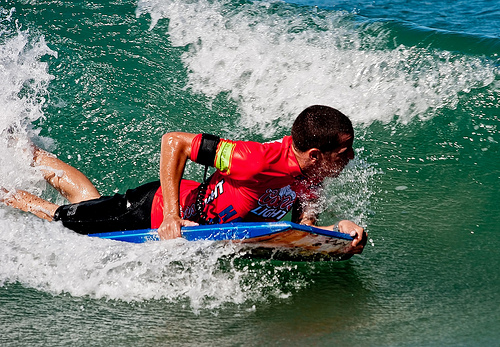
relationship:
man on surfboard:
[4, 100, 356, 226] [90, 223, 360, 258]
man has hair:
[4, 100, 356, 226] [285, 104, 358, 144]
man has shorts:
[4, 100, 356, 226] [53, 167, 161, 238]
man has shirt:
[4, 100, 356, 226] [148, 127, 312, 233]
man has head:
[4, 100, 356, 226] [288, 97, 361, 181]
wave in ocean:
[170, 12, 489, 121] [13, 20, 499, 331]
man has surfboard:
[4, 100, 356, 226] [90, 223, 360, 258]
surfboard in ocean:
[90, 223, 360, 258] [13, 20, 499, 331]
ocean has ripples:
[13, 20, 499, 331] [381, 217, 491, 276]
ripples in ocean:
[381, 217, 491, 276] [13, 20, 499, 331]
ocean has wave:
[13, 20, 499, 331] [170, 12, 489, 121]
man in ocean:
[4, 100, 356, 226] [13, 20, 499, 331]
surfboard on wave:
[90, 223, 360, 258] [170, 12, 489, 121]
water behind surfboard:
[5, 40, 65, 289] [90, 223, 360, 258]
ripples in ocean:
[28, 305, 181, 343] [13, 20, 499, 331]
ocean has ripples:
[13, 20, 499, 331] [97, 41, 165, 103]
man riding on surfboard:
[4, 100, 356, 226] [90, 223, 360, 258]